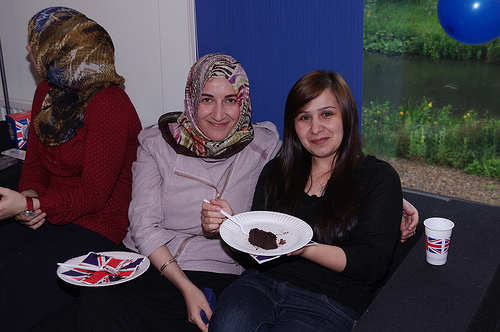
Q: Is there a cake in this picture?
A: Yes, there is a cake.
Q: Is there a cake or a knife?
A: Yes, there is a cake.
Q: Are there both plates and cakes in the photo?
A: Yes, there are both a cake and plates.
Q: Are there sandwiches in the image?
A: No, there are no sandwiches.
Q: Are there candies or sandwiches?
A: No, there are no sandwiches or candies.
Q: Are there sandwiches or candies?
A: No, there are no sandwiches or candies.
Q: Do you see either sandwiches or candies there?
A: No, there are no sandwiches or candies.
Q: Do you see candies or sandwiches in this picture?
A: No, there are no sandwiches or candies.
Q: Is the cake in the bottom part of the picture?
A: Yes, the cake is in the bottom of the image.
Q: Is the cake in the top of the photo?
A: No, the cake is in the bottom of the image.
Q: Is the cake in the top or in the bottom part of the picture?
A: The cake is in the bottom of the image.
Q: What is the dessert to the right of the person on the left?
A: The dessert is a cake.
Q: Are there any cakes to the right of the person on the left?
A: Yes, there is a cake to the right of the person.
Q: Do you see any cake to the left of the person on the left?
A: No, the cake is to the right of the person.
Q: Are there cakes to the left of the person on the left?
A: No, the cake is to the right of the person.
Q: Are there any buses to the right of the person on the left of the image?
A: No, there is a cake to the right of the person.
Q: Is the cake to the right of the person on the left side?
A: Yes, the cake is to the right of the person.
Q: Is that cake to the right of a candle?
A: No, the cake is to the right of the person.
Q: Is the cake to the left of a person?
A: No, the cake is to the right of a person.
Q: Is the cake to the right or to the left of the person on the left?
A: The cake is to the right of the person.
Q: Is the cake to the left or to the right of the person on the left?
A: The cake is to the right of the person.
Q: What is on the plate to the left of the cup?
A: The cake is on the plate.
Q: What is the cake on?
A: The cake is on the plate.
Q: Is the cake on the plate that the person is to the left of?
A: Yes, the cake is on the plate.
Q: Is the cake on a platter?
A: No, the cake is on the plate.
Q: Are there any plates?
A: Yes, there is a plate.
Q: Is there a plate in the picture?
A: Yes, there is a plate.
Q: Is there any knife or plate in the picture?
A: Yes, there is a plate.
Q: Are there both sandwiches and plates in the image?
A: No, there is a plate but no sandwiches.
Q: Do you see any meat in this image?
A: No, there is no meat.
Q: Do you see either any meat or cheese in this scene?
A: No, there are no meat or cheese.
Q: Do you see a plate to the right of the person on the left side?
A: Yes, there is a plate to the right of the person.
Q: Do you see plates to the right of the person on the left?
A: Yes, there is a plate to the right of the person.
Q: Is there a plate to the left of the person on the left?
A: No, the plate is to the right of the person.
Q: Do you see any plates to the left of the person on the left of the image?
A: No, the plate is to the right of the person.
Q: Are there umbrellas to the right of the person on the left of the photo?
A: No, there is a plate to the right of the person.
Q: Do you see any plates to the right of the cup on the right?
A: No, the plate is to the left of the cup.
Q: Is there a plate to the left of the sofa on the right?
A: Yes, there is a plate to the left of the sofa.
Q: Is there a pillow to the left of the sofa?
A: No, there is a plate to the left of the sofa.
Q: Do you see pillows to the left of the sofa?
A: No, there is a plate to the left of the sofa.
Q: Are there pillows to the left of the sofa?
A: No, there is a plate to the left of the sofa.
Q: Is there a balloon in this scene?
A: Yes, there is a balloon.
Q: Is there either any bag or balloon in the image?
A: Yes, there is a balloon.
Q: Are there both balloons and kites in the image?
A: No, there is a balloon but no kites.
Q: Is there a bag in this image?
A: No, there are no bags.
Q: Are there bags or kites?
A: No, there are no bags or kites.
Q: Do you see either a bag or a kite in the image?
A: No, there are no bags or kites.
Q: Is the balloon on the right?
A: Yes, the balloon is on the right of the image.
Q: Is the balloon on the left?
A: No, the balloon is on the right of the image.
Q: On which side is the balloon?
A: The balloon is on the right of the image.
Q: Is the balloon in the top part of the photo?
A: Yes, the balloon is in the top of the image.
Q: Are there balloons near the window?
A: Yes, there is a balloon near the window.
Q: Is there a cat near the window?
A: No, there is a balloon near the window.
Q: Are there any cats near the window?
A: No, there is a balloon near the window.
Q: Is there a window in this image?
A: Yes, there is a window.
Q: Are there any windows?
A: Yes, there is a window.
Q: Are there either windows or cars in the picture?
A: Yes, there is a window.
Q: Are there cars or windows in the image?
A: Yes, there is a window.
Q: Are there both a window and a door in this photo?
A: No, there is a window but no doors.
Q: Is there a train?
A: No, there are no trains.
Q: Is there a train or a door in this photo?
A: No, there are no trains or doors.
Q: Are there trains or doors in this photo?
A: No, there are no trains or doors.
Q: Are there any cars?
A: No, there are no cars.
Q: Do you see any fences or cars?
A: No, there are no cars or fences.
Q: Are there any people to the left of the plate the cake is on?
A: Yes, there is a person to the left of the plate.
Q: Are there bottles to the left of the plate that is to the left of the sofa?
A: No, there is a person to the left of the plate.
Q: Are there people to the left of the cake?
A: Yes, there is a person to the left of the cake.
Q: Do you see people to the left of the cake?
A: Yes, there is a person to the left of the cake.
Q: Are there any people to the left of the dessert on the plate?
A: Yes, there is a person to the left of the cake.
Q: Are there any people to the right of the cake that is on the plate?
A: No, the person is to the left of the cake.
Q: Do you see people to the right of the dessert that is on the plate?
A: No, the person is to the left of the cake.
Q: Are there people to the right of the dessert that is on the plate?
A: No, the person is to the left of the cake.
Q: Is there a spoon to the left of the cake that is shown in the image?
A: No, there is a person to the left of the cake.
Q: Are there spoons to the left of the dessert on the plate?
A: No, there is a person to the left of the cake.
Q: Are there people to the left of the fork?
A: Yes, there is a person to the left of the fork.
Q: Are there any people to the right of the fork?
A: No, the person is to the left of the fork.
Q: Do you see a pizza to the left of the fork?
A: No, there is a person to the left of the fork.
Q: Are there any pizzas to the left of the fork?
A: No, there is a person to the left of the fork.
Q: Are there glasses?
A: No, there are no glasses.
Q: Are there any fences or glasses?
A: No, there are no glasses or fences.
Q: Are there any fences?
A: No, there are no fences.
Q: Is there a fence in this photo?
A: No, there are no fences.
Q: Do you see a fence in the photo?
A: No, there are no fences.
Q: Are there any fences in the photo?
A: No, there are no fences.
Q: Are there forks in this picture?
A: Yes, there is a fork.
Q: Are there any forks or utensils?
A: Yes, there is a fork.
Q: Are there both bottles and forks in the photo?
A: No, there is a fork but no bottles.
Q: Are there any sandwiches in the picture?
A: No, there are no sandwiches.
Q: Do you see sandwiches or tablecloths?
A: No, there are no sandwiches or tablecloths.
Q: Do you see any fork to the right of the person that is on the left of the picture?
A: Yes, there is a fork to the right of the person.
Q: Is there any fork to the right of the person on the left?
A: Yes, there is a fork to the right of the person.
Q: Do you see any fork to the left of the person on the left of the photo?
A: No, the fork is to the right of the person.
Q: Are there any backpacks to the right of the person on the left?
A: No, there is a fork to the right of the person.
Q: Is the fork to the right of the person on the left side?
A: Yes, the fork is to the right of the person.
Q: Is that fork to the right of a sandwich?
A: No, the fork is to the right of the person.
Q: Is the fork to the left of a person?
A: No, the fork is to the right of a person.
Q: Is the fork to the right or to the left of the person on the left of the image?
A: The fork is to the right of the person.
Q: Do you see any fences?
A: No, there are no fences.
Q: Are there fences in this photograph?
A: No, there are no fences.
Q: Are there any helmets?
A: No, there are no helmets.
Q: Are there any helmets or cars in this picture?
A: No, there are no helmets or cars.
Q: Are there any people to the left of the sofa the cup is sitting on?
A: Yes, there is a person to the left of the sofa.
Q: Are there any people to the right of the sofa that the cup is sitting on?
A: No, the person is to the left of the sofa.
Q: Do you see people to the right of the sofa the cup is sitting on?
A: No, the person is to the left of the sofa.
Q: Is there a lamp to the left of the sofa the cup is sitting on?
A: No, there is a person to the left of the sofa.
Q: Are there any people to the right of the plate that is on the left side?
A: Yes, there is a person to the right of the plate.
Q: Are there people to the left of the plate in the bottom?
A: No, the person is to the right of the plate.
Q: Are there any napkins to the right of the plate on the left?
A: No, there is a person to the right of the plate.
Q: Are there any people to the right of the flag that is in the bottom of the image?
A: Yes, there is a person to the right of the flag.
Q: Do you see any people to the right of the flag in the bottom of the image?
A: Yes, there is a person to the right of the flag.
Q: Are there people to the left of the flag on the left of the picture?
A: No, the person is to the right of the flag.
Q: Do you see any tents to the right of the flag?
A: No, there is a person to the right of the flag.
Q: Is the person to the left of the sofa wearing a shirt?
A: Yes, the person is wearing a shirt.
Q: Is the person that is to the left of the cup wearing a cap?
A: No, the person is wearing a shirt.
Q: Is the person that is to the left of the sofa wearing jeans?
A: Yes, the person is wearing jeans.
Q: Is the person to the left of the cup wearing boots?
A: No, the person is wearing jeans.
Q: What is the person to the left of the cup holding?
A: The person is holding the fork.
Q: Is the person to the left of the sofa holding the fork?
A: Yes, the person is holding the fork.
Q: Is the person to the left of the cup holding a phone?
A: No, the person is holding the fork.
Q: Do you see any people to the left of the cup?
A: Yes, there is a person to the left of the cup.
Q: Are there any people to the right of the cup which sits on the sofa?
A: No, the person is to the left of the cup.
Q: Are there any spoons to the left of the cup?
A: No, there is a person to the left of the cup.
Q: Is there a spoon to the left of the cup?
A: No, there is a person to the left of the cup.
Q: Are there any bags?
A: No, there are no bags.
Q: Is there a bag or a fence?
A: No, there are no bags or fences.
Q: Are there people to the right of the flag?
A: Yes, there is a person to the right of the flag.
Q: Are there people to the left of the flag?
A: No, the person is to the right of the flag.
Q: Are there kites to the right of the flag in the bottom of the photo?
A: No, there is a person to the right of the flag.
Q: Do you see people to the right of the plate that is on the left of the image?
A: Yes, there is a person to the right of the plate.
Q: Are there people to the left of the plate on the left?
A: No, the person is to the right of the plate.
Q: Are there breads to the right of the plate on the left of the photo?
A: No, there is a person to the right of the plate.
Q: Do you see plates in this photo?
A: Yes, there is a plate.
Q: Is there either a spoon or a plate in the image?
A: Yes, there is a plate.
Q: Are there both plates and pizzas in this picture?
A: No, there is a plate but no pizzas.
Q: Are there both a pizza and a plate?
A: No, there is a plate but no pizzas.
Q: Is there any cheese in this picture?
A: No, there is no cheese.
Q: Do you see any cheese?
A: No, there is no cheese.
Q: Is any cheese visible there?
A: No, there is no cheese.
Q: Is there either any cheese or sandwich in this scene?
A: No, there are no cheese or sandwiches.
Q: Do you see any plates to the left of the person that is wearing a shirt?
A: Yes, there is a plate to the left of the person.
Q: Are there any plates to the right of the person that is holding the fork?
A: No, the plate is to the left of the person.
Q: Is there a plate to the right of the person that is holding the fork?
A: No, the plate is to the left of the person.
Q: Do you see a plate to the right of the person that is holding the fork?
A: No, the plate is to the left of the person.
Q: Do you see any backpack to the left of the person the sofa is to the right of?
A: No, there is a plate to the left of the person.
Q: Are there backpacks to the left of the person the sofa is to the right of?
A: No, there is a plate to the left of the person.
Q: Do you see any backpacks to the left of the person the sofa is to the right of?
A: No, there is a plate to the left of the person.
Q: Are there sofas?
A: Yes, there is a sofa.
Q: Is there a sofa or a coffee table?
A: Yes, there is a sofa.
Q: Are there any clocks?
A: No, there are no clocks.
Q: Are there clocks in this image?
A: No, there are no clocks.